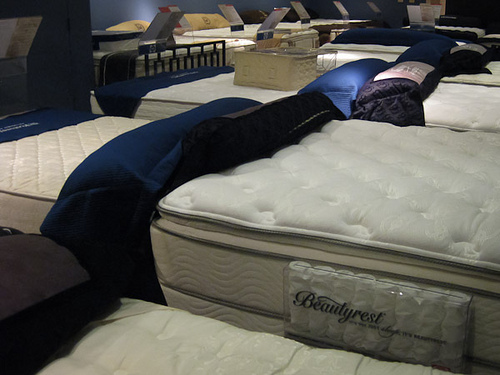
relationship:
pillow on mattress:
[40, 97, 265, 306] [0, 105, 157, 238]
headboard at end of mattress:
[144, 40, 227, 78] [93, 48, 224, 91]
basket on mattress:
[235, 45, 317, 91] [90, 66, 356, 118]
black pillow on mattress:
[350, 59, 444, 126] [90, 66, 356, 118]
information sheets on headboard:
[138, 7, 186, 56] [144, 40, 227, 78]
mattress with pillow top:
[150, 117, 499, 373] [157, 118, 500, 284]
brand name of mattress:
[293, 289, 450, 350] [150, 117, 499, 373]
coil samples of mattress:
[285, 259, 474, 374] [150, 117, 499, 373]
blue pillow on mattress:
[297, 58, 392, 119] [90, 66, 356, 118]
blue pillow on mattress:
[40, 97, 265, 306] [0, 105, 157, 238]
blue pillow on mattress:
[331, 28, 459, 46] [321, 42, 462, 54]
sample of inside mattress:
[285, 259, 474, 374] [150, 117, 499, 373]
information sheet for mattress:
[138, 7, 186, 56] [93, 48, 224, 91]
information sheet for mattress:
[253, 7, 292, 41] [175, 34, 257, 64]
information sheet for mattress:
[217, 4, 245, 33] [184, 24, 320, 48]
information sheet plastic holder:
[407, 4, 435, 25] [409, 24, 436, 33]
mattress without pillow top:
[0, 105, 157, 238] [157, 118, 500, 284]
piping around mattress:
[151, 222, 499, 306] [150, 117, 499, 373]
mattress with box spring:
[150, 117, 499, 373] [160, 285, 500, 374]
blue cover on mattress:
[95, 67, 234, 119] [90, 66, 356, 118]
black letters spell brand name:
[292, 289, 383, 332] [293, 289, 450, 350]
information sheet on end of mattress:
[253, 7, 292, 41] [184, 24, 320, 48]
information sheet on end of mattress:
[217, 4, 245, 33] [184, 24, 320, 48]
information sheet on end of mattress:
[138, 7, 186, 56] [175, 34, 257, 64]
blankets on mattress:
[0, 106, 109, 144] [0, 105, 157, 238]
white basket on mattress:
[235, 45, 317, 91] [90, 66, 356, 118]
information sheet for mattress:
[1, 17, 46, 113] [0, 105, 157, 238]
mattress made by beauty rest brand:
[150, 117, 499, 373] [292, 289, 383, 332]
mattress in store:
[150, 117, 499, 373] [0, 17, 499, 375]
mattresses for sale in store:
[0, 17, 499, 375] [0, 17, 499, 375]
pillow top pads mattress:
[157, 118, 500, 284] [150, 117, 499, 373]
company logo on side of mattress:
[292, 289, 383, 332] [150, 117, 499, 373]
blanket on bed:
[95, 67, 234, 119] [90, 66, 356, 118]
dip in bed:
[258, 207, 279, 226] [150, 117, 499, 373]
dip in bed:
[347, 223, 373, 242] [150, 117, 499, 373]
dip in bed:
[451, 238, 479, 259] [150, 117, 499, 373]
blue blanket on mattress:
[95, 67, 234, 119] [90, 66, 356, 118]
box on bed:
[235, 45, 317, 91] [90, 66, 356, 118]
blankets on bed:
[0, 106, 109, 144] [0, 105, 157, 238]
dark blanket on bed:
[95, 67, 234, 119] [90, 66, 356, 118]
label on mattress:
[285, 259, 474, 374] [150, 117, 499, 373]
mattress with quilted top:
[150, 117, 499, 373] [157, 118, 500, 284]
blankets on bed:
[1, 66, 236, 150] [0, 64, 300, 237]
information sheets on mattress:
[138, 7, 186, 56] [175, 34, 257, 64]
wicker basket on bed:
[235, 45, 317, 91] [90, 66, 356, 118]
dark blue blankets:
[95, 67, 234, 119] [0, 106, 109, 144]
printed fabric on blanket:
[371, 61, 436, 86] [350, 59, 444, 126]